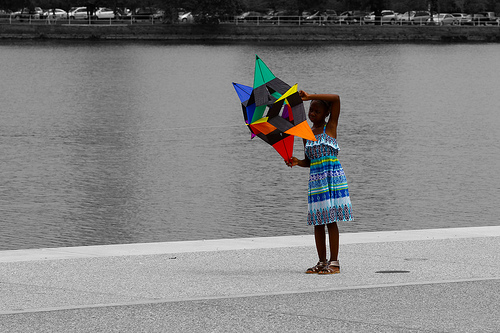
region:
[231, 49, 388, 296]
Girl on the sidewalk.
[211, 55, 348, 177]
Girl holding a kite.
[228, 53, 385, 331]
Girl in a sundress.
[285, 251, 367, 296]
Sandals on the girl.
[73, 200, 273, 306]
Water by the sidewalk.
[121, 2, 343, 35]
Cars in the background.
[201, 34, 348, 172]
Colorful kite in the girl's hands.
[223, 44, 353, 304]
Young girl with a kite.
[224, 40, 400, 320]
Young girl on the sidewalk.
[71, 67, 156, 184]
Ripples on the water.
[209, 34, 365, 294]
Little girl holding a kite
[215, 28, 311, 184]
Colorful kite in the girl's hand.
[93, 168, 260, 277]
Water against the sidewalk.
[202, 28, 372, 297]
Multi-colored kit with the girl.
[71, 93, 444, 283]
Ripples in the water.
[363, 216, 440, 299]
Shadow on the sidewalk.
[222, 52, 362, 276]
a girl preparing to fly a kite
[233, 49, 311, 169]
a kite of different colors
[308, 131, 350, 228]
a colorful dress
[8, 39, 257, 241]
a very large lake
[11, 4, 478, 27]
many cars in the distance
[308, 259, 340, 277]
a couple of nice sandals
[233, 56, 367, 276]
a girl holding a kite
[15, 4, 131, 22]
four car in the parking slot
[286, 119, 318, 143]
an orange triangle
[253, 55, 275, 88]
a green triangle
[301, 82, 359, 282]
The girls is standing.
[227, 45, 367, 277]
The girl is holding a kite.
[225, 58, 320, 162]
The kite is colorful.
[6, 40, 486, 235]
The water is clear.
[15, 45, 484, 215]
The water is calm.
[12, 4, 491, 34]
The cars are parked.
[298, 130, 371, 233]
The dress is blue.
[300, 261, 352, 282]
Her sandles are gold.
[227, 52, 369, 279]
She is holding a kite.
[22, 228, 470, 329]
The concrete is grey.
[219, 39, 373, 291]
little girl holding a kite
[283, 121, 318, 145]
orange triangle on the kite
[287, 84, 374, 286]
little girl wearing a dress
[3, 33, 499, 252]
calm body of water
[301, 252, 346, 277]
sandals on the feet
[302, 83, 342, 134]
arm rasied above head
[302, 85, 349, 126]
arm bent at the elbow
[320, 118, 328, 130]
thin strap of the dress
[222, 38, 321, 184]
multicolored kite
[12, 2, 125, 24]
row of parked cars